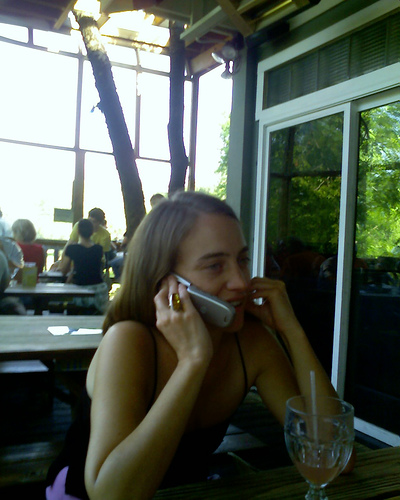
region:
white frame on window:
[233, 90, 328, 129]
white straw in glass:
[308, 371, 328, 458]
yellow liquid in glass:
[280, 446, 360, 482]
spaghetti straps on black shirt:
[142, 326, 160, 394]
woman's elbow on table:
[64, 464, 145, 498]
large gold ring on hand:
[153, 282, 198, 324]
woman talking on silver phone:
[148, 268, 244, 331]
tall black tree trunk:
[81, 68, 154, 195]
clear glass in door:
[281, 152, 334, 259]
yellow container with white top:
[15, 254, 52, 286]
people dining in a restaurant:
[18, 172, 358, 494]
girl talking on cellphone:
[143, 190, 280, 334]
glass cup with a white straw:
[274, 359, 362, 497]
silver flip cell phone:
[149, 273, 242, 323]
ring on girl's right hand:
[161, 284, 195, 321]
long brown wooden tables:
[5, 293, 112, 366]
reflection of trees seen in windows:
[275, 177, 395, 251]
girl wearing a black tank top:
[64, 318, 274, 486]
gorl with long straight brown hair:
[89, 184, 249, 336]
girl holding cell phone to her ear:
[107, 188, 297, 362]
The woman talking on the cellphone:
[159, 268, 264, 353]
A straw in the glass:
[276, 354, 338, 463]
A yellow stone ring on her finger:
[162, 289, 186, 313]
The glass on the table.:
[285, 373, 367, 498]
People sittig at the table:
[6, 209, 111, 296]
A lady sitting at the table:
[97, 269, 350, 495]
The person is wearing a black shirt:
[67, 242, 104, 286]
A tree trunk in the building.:
[85, 39, 197, 204]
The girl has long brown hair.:
[117, 200, 188, 329]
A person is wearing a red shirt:
[9, 235, 54, 276]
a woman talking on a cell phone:
[152, 196, 256, 354]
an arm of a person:
[271, 295, 337, 392]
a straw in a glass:
[286, 366, 361, 496]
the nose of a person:
[225, 265, 250, 295]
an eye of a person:
[198, 255, 226, 276]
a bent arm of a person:
[78, 370, 180, 498]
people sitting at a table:
[0, 204, 118, 304]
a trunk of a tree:
[160, 23, 192, 191]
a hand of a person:
[249, 272, 298, 326]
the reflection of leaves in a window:
[338, 120, 399, 248]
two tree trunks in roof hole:
[77, 6, 191, 228]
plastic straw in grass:
[284, 369, 353, 493]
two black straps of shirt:
[142, 327, 256, 427]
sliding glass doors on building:
[255, 98, 395, 424]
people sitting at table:
[9, 218, 103, 284]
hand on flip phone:
[155, 277, 229, 331]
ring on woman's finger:
[167, 289, 183, 315]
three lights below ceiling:
[213, 38, 241, 84]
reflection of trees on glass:
[269, 103, 398, 255]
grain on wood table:
[163, 450, 395, 499]